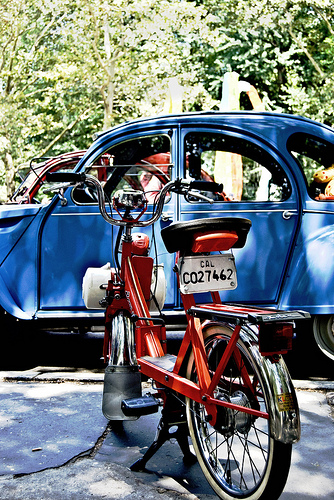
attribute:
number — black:
[220, 267, 227, 282]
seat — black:
[160, 215, 252, 252]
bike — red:
[36, 137, 299, 495]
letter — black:
[203, 258, 210, 268]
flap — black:
[97, 362, 150, 422]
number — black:
[221, 269, 227, 283]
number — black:
[191, 269, 205, 287]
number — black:
[206, 267, 212, 285]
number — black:
[211, 269, 219, 283]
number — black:
[220, 268, 227, 285]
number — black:
[225, 265, 236, 285]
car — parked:
[2, 109, 332, 377]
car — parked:
[7, 147, 234, 206]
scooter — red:
[36, 150, 295, 491]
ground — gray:
[0, 364, 332, 499]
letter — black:
[180, 269, 190, 288]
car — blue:
[1, 113, 332, 329]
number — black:
[202, 266, 215, 279]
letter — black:
[197, 256, 206, 272]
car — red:
[5, 151, 228, 210]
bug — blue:
[1, 107, 331, 376]